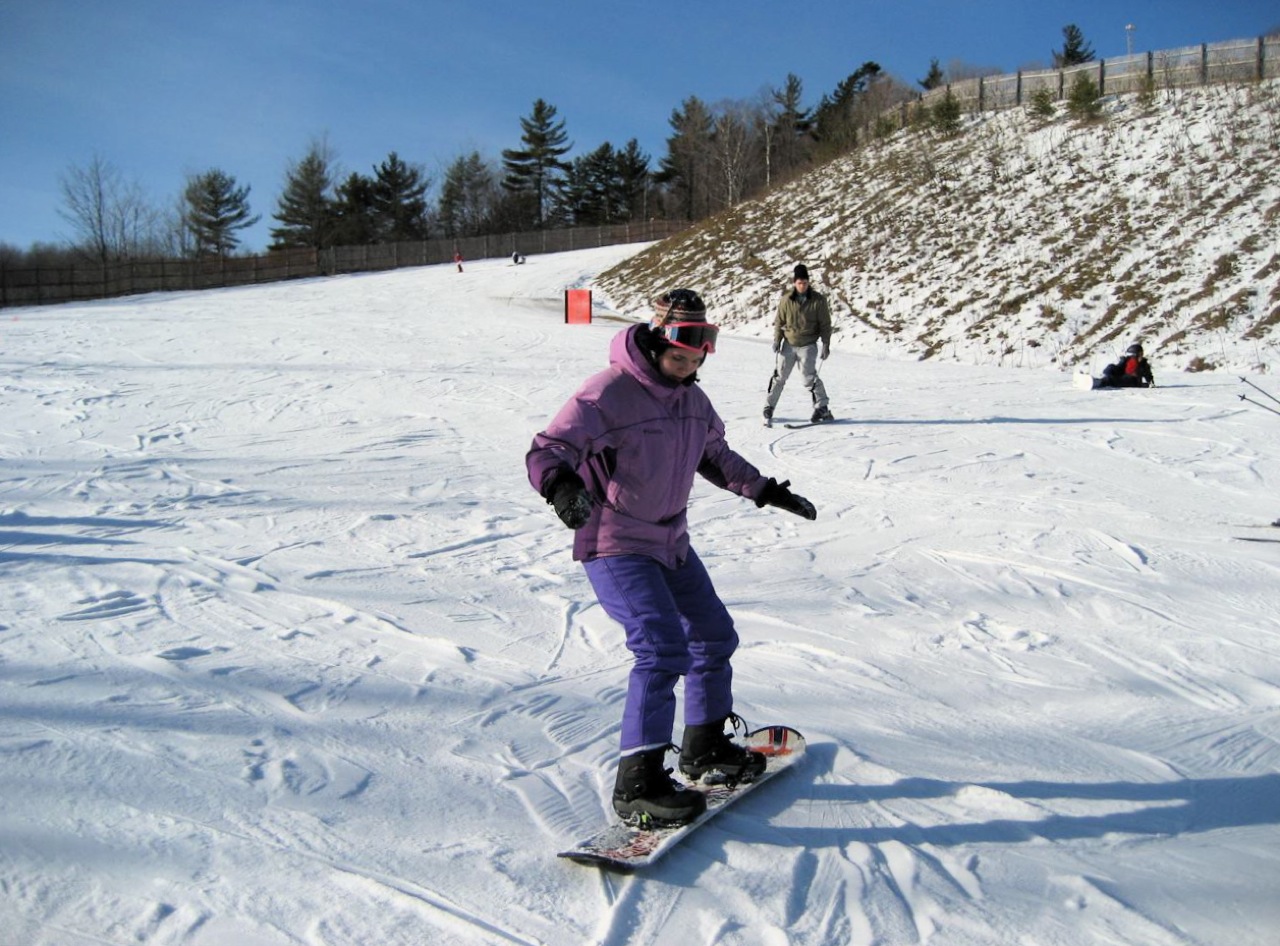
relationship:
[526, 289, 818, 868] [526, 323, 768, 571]
boarder wearing coat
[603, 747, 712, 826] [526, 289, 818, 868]
shoe on boarder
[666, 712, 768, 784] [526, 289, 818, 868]
shoe on boarder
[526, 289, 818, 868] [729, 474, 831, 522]
boarder wearing glove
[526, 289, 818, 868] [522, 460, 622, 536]
boarder wearing glove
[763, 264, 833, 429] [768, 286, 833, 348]
man wearing jacket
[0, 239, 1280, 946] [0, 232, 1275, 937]
snow on snow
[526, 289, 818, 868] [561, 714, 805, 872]
boarder on snowboard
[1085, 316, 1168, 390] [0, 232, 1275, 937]
person sitting on snow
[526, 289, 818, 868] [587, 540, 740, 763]
boarder wearing pants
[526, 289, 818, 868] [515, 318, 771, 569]
boarder wearing coat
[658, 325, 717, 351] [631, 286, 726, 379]
goggles on head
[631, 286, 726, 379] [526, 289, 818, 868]
head on boarder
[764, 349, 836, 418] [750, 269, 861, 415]
pants on man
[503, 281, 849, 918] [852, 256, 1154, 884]
boarder going down hill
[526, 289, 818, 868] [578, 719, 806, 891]
boarder standing snowboard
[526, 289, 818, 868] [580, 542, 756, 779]
boarder wearing pants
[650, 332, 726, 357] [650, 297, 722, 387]
goggles on face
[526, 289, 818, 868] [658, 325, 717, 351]
boarder wearing goggles